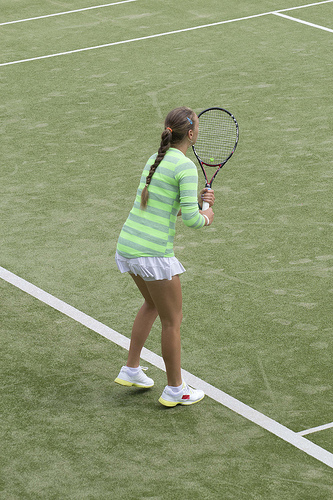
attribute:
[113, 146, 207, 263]
top — green, grey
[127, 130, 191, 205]
braid — long, brown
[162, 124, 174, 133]
hairband — orange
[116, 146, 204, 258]
shirt — green, long-sleeve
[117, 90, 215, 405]
player — light-skinned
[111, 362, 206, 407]
tennis shoes — white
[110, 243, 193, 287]
skirt — white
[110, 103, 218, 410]
woman — grey, yellow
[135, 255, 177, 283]
shorts — white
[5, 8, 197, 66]
lines — white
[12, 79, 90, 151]
ground — green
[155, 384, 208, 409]
shoe — white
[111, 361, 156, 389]
shoe — white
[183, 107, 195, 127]
barrette — blue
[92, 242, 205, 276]
skort — white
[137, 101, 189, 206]
hair — brown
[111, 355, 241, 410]
tennis shoes — white